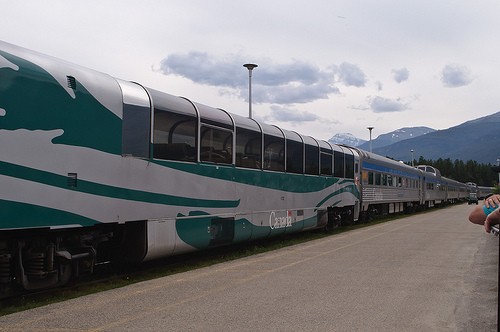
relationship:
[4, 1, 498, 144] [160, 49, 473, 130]
sky has clouds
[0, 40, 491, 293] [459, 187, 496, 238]
train for passengers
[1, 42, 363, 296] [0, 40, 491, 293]
car of a train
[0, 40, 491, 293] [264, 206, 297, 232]
train has text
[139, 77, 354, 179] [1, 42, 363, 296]
windows on car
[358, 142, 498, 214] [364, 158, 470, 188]
cars have blue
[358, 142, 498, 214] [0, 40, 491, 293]
cars of train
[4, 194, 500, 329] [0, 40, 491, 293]
platform by train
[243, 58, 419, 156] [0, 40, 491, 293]
lights over train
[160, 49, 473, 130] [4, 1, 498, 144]
clouds in sky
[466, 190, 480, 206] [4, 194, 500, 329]
cart on platform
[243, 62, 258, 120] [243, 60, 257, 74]
pole for light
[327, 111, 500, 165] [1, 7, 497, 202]
mountains in background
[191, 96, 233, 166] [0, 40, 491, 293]
window on train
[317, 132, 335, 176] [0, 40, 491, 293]
window on train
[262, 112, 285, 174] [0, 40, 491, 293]
window on train